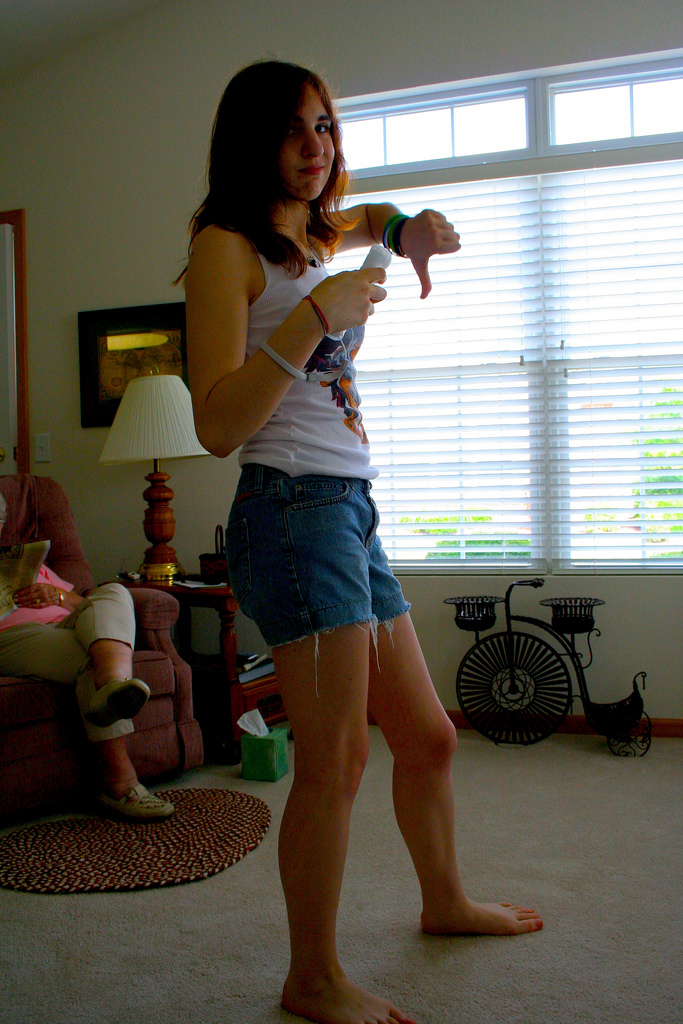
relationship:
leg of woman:
[256, 561, 377, 1021] [155, 39, 559, 1015]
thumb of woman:
[408, 264, 437, 303] [155, 39, 559, 1015]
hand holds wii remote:
[307, 265, 391, 327] [326, 230, 398, 359]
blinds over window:
[339, 41, 681, 585] [312, 51, 682, 565]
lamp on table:
[90, 365, 216, 567] [135, 565, 256, 763]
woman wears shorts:
[155, 39, 559, 1015] [214, 454, 415, 652]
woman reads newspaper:
[1, 498, 179, 825] [1, 530, 55, 602]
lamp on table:
[90, 366, 216, 567] [125, 570, 246, 738]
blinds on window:
[339, 41, 681, 584] [334, 39, 681, 580]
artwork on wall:
[68, 297, 199, 436] [23, 48, 194, 527]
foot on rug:
[90, 764, 176, 823] [9, 779, 274, 898]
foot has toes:
[416, 895, 545, 939] [495, 888, 549, 932]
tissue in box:
[230, 697, 272, 736] [237, 727, 291, 784]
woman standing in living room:
[155, 39, 559, 1015] [22, 17, 660, 1005]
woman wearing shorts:
[155, 39, 559, 1015] [214, 453, 415, 651]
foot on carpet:
[416, 895, 545, 939] [9, 691, 659, 1005]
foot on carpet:
[274, 968, 420, 1007] [9, 691, 659, 1005]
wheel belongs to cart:
[456, 633, 572, 744] [439, 567, 652, 760]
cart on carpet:
[439, 567, 652, 760] [9, 691, 659, 1005]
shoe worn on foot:
[98, 781, 177, 820] [106, 779, 178, 819]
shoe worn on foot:
[81, 674, 153, 732] [79, 671, 154, 739]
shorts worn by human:
[214, 453, 415, 651] [170, 52, 542, 1006]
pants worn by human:
[14, 577, 138, 742] [12, 495, 185, 822]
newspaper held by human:
[12, 537, 54, 595] [12, 495, 185, 822]